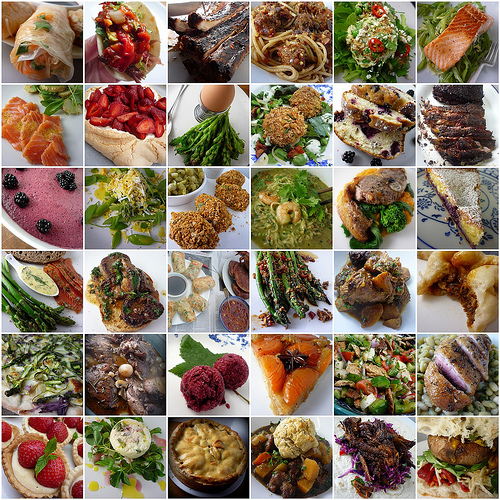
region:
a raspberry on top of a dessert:
[13, 189, 33, 210]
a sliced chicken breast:
[419, 334, 498, 411]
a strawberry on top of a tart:
[34, 455, 68, 489]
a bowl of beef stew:
[246, 419, 329, 496]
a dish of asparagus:
[254, 251, 331, 329]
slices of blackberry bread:
[332, 83, 414, 158]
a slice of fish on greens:
[422, 3, 489, 70]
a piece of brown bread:
[9, 246, 67, 263]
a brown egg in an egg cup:
[196, 84, 236, 110]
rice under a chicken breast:
[416, 332, 498, 413]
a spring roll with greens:
[2, 1, 82, 82]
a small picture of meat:
[166, 0, 249, 82]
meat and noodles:
[252, 1, 331, 81]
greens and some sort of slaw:
[331, 3, 417, 83]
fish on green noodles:
[416, 1, 498, 89]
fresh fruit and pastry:
[85, 86, 168, 167]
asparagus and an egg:
[167, 83, 249, 165]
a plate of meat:
[418, 83, 498, 167]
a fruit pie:
[250, 335, 338, 417]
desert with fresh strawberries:
[0, 416, 78, 499]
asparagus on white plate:
[256, 254, 330, 329]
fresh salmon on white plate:
[1, 98, 84, 163]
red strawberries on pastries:
[1, 420, 78, 499]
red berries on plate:
[173, 340, 248, 411]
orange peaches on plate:
[254, 337, 327, 416]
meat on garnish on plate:
[422, 337, 498, 407]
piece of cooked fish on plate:
[420, 8, 499, 75]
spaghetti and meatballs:
[259, 5, 336, 72]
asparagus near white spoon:
[0, 253, 77, 329]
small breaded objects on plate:
[168, 170, 243, 245]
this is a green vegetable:
[7, 271, 64, 331]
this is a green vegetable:
[176, 117, 242, 159]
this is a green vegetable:
[97, 448, 133, 485]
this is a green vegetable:
[90, 202, 137, 235]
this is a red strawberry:
[13, 431, 73, 493]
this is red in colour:
[91, 81, 175, 144]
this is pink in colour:
[21, 176, 78, 229]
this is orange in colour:
[257, 338, 334, 405]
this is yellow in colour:
[85, 472, 112, 499]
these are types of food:
[28, 5, 481, 480]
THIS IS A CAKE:
[5, 165, 81, 243]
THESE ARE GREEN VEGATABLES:
[3, 260, 78, 322]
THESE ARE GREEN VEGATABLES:
[255, 255, 325, 320]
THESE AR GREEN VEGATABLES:
[182, 111, 239, 156]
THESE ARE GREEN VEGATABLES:
[30, 335, 60, 380]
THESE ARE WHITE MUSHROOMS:
[165, 430, 250, 461]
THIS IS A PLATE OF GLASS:
[426, 205, 440, 230]